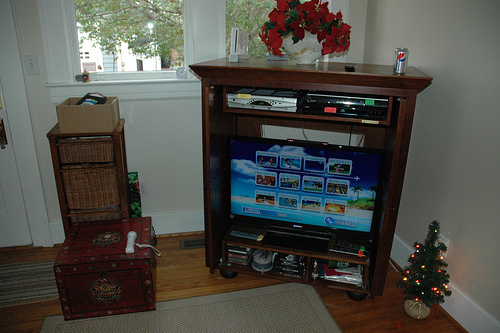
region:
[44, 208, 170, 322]
Red box in a room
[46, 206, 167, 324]
red box is close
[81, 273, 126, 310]
Design on red box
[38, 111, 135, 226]
Shelf with baskets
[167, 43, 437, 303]
Shelf on the corner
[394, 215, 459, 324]
Christmas tree is small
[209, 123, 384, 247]
Television on the shelf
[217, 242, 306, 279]
CDs on the bottom of shelf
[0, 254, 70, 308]
Mat in front of door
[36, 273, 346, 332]
Carpet is tan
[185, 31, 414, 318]
television stand in corner of room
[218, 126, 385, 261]
flat screen television on stand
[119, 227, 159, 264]
wii remote laying on trunk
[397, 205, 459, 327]
small lighted christmas tree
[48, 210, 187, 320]
small square red trunk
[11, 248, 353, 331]
two rugs on floor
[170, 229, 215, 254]
vent in wooden floor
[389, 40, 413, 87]
soda can on television stand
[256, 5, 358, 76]
poinsettia in white vase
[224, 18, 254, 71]
wii gaming system on television stand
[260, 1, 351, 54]
Red flowers in white vase.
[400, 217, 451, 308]
Christmas tree in the corner on the floor.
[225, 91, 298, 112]
Cable box on the shelf in wood entertainment center.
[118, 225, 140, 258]
White Wii remote on wooden box.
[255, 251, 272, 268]
CDs in round holder on bottom shelf of wooden entertainment center.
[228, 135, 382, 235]
Black flat screen TV inside of entertainment center.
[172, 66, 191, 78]
Little white clock on window sill.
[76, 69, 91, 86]
Ornament on the left of the window sill.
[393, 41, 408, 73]
Pepsi can on top of the wooden entertainment center.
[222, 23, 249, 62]
Wii console on top of wooden entertainment center.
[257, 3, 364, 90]
Red flowers on a TV stand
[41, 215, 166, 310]
Brown box on a floor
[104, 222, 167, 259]
Wii remote on a box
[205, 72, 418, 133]
Cable box on a TV stand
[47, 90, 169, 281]
Cardboard box on a stand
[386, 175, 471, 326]
Tiny Christmas tree on the floor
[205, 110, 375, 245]
TV in a stand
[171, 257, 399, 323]
Rug on a wood floor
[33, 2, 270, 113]
Window in a room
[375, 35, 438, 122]
Pepsi can on a TV stand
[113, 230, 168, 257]
a wii remote on a chest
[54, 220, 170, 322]
a red floral chest on the floor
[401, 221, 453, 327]
a mini christmas tree sitting on the floor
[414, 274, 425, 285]
twinkling lights on a tiny tree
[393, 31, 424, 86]
a soda can on a stand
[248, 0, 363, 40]
red flowers in a white vase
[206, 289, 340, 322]
a beige rug on the wood floor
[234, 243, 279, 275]
Cds stacked on a shelf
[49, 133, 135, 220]
a wooden stand with wicker baskets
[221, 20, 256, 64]
a game console on a stand